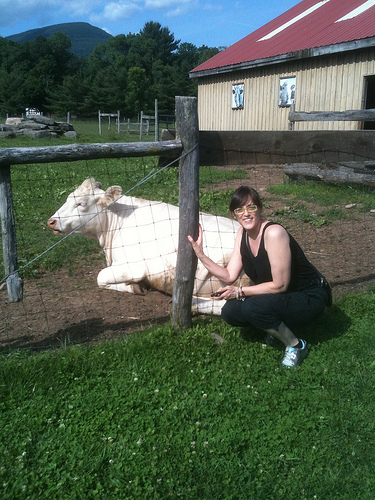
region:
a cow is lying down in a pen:
[50, 173, 257, 317]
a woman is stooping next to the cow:
[157, 180, 334, 371]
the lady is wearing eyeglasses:
[230, 200, 260, 220]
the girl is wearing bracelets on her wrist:
[231, 281, 250, 301]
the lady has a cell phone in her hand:
[208, 188, 300, 305]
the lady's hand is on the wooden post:
[178, 184, 274, 317]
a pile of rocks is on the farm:
[2, 110, 75, 154]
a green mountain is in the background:
[2, 19, 304, 178]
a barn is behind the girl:
[186, 0, 374, 372]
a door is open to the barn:
[352, 69, 374, 170]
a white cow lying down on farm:
[46, 174, 257, 316]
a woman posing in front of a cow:
[186, 185, 334, 368]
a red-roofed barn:
[187, 0, 373, 166]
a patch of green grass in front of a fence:
[0, 287, 372, 498]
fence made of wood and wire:
[0, 96, 373, 330]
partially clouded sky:
[1, 1, 299, 49]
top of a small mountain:
[2, 20, 117, 54]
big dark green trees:
[0, 19, 230, 122]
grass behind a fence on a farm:
[0, 120, 373, 278]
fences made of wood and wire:
[0, 108, 176, 139]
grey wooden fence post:
[170, 91, 203, 351]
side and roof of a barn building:
[185, 0, 374, 148]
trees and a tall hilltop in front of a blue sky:
[0, 0, 160, 84]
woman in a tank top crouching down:
[185, 184, 337, 373]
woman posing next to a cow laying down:
[45, 170, 337, 368]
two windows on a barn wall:
[198, 71, 326, 130]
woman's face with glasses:
[227, 184, 262, 232]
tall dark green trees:
[122, 17, 174, 118]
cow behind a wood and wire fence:
[2, 135, 184, 327]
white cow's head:
[42, 173, 120, 241]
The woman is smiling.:
[225, 178, 266, 236]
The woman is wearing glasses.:
[221, 180, 266, 234]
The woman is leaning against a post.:
[167, 92, 337, 370]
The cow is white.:
[39, 168, 252, 312]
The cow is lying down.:
[45, 166, 257, 323]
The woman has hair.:
[223, 179, 271, 240]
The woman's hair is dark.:
[224, 180, 285, 257]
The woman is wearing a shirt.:
[184, 183, 334, 372]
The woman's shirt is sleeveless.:
[185, 182, 331, 300]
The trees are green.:
[0, 17, 224, 123]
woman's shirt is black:
[220, 216, 311, 284]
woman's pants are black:
[226, 281, 348, 352]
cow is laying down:
[49, 172, 264, 332]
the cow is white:
[37, 157, 245, 349]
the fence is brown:
[16, 81, 342, 341]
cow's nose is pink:
[33, 201, 63, 231]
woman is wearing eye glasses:
[230, 196, 270, 220]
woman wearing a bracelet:
[234, 282, 246, 311]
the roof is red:
[189, 1, 372, 81]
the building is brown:
[196, 63, 372, 150]